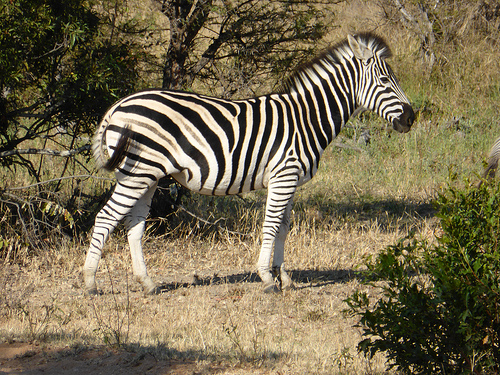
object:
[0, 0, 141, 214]
tree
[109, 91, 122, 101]
leaf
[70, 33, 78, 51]
leaf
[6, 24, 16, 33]
leaves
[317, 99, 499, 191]
grass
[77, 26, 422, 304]
zebra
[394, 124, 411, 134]
mouth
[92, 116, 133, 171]
tail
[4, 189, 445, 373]
ground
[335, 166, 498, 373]
bush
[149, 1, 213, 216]
tree trunk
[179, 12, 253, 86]
branch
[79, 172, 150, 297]
leg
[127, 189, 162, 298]
leg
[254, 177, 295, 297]
leg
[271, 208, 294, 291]
leg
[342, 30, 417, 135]
head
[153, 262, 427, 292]
shadow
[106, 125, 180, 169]
stripe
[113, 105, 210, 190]
stripe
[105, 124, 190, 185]
stripe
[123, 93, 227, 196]
stripe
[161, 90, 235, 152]
stripe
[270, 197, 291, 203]
stripe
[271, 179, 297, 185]
stripe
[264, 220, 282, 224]
stripe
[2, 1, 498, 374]
field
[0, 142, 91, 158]
branch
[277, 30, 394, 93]
mane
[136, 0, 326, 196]
tree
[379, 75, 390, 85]
eye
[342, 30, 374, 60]
ear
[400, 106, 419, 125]
nose